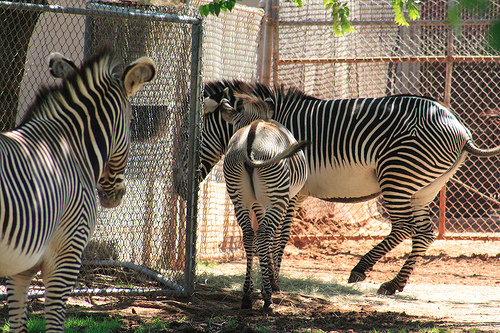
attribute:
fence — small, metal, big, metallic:
[277, 30, 481, 73]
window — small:
[135, 103, 169, 145]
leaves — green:
[317, 2, 424, 39]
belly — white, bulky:
[312, 169, 373, 196]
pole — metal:
[445, 52, 455, 103]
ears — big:
[38, 48, 160, 97]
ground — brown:
[303, 299, 349, 323]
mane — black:
[80, 61, 115, 86]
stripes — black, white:
[64, 109, 103, 131]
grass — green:
[77, 316, 119, 332]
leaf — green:
[321, 6, 353, 40]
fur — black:
[332, 100, 339, 117]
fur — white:
[353, 104, 356, 114]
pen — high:
[30, 20, 493, 181]